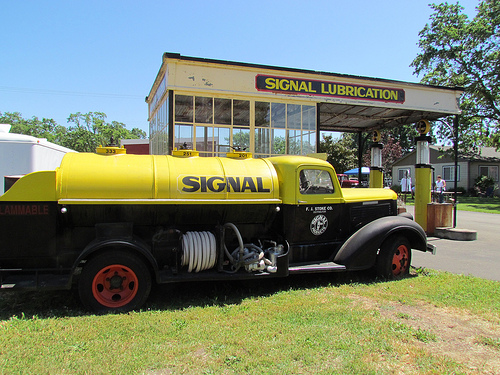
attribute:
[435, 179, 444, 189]
shirt — white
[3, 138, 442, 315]
truck — white, black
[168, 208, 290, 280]
system — oil, delivery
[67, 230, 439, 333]
rims — red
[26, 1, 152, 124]
sky — clear, blue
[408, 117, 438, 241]
gas pump — antique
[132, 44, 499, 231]
station — very small, gas station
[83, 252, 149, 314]
wheel — red, rear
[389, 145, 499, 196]
singlestory house — brown, single-story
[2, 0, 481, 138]
sky — blue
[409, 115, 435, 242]
pump — yellow, black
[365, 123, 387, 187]
pump — yellow, black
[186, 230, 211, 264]
hose — white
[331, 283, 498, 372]
patch — worn out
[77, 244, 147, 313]
wheel — black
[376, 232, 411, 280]
wheel — black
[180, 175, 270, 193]
company name — black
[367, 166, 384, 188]
pylon — yellow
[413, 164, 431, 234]
pylon — yellow